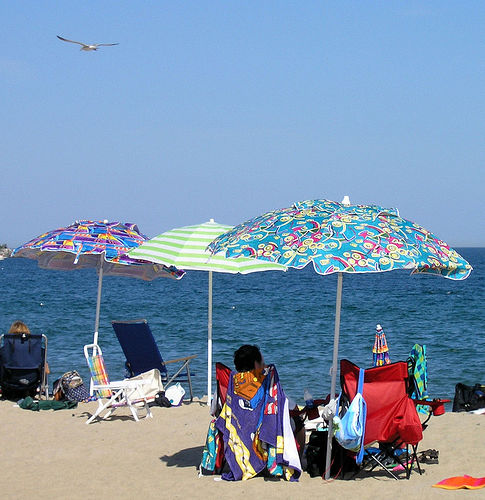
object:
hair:
[233, 344, 263, 373]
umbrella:
[372, 324, 393, 367]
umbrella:
[204, 195, 473, 282]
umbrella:
[4, 216, 183, 279]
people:
[210, 344, 299, 432]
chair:
[312, 356, 451, 480]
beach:
[0, 395, 485, 499]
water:
[0, 247, 485, 413]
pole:
[325, 196, 352, 482]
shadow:
[159, 445, 205, 474]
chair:
[108, 320, 198, 407]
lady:
[9, 321, 50, 376]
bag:
[452, 382, 485, 413]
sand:
[0, 395, 485, 500]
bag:
[317, 397, 339, 420]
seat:
[314, 356, 447, 481]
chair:
[82, 342, 163, 425]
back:
[84, 344, 112, 398]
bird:
[56, 35, 121, 52]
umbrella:
[130, 218, 289, 407]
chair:
[214, 342, 453, 479]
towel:
[200, 364, 300, 480]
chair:
[211, 362, 313, 486]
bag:
[333, 366, 368, 466]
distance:
[0, 241, 484, 255]